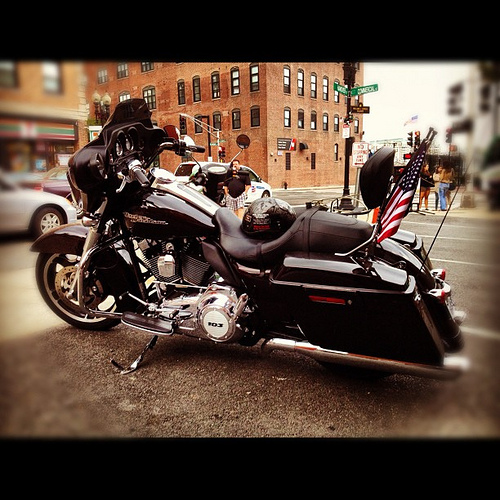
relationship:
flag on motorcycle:
[376, 138, 428, 243] [29, 97, 469, 377]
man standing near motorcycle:
[220, 158, 251, 220] [29, 97, 469, 377]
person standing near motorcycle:
[416, 160, 434, 212] [29, 97, 469, 377]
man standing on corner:
[220, 158, 251, 220] [412, 201, 464, 221]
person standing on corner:
[416, 160, 434, 212] [412, 201, 464, 221]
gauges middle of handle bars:
[113, 131, 146, 157] [118, 126, 202, 191]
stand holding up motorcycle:
[106, 340, 166, 377] [33, 77, 482, 409]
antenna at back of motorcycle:
[416, 151, 471, 273] [29, 97, 469, 377]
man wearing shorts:
[223, 157, 245, 221] [225, 193, 250, 208]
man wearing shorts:
[220, 158, 251, 220] [217, 180, 257, 212]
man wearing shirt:
[220, 158, 251, 220] [416, 170, 434, 184]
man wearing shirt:
[220, 158, 251, 220] [212, 170, 255, 198]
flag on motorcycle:
[381, 163, 429, 233] [29, 97, 469, 377]